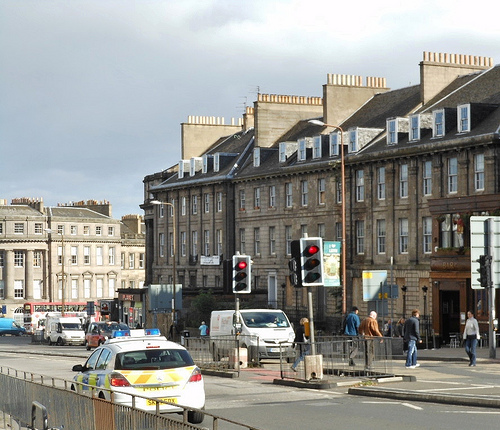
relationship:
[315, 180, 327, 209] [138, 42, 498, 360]
window on building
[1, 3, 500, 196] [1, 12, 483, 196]
cloud in sky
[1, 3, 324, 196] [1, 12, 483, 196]
cloud in sky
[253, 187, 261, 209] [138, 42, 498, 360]
window on building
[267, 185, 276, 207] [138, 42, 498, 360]
window on building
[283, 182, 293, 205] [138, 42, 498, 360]
window on building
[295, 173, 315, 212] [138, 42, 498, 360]
window on building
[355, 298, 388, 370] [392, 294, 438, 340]
person wearing a jacket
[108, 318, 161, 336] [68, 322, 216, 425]
lights on car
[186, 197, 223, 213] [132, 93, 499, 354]
window on building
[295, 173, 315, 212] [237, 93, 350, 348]
window on building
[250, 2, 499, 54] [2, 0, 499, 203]
light in sky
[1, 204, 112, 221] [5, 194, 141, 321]
roof on building